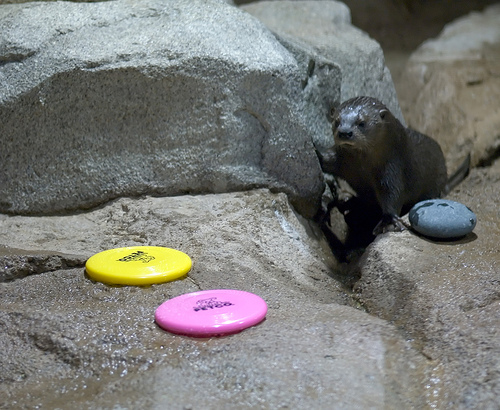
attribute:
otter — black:
[316, 91, 453, 241]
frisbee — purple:
[148, 277, 277, 352]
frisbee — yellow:
[82, 243, 194, 288]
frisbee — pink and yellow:
[81, 241, 196, 284]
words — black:
[187, 286, 231, 316]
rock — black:
[407, 196, 479, 241]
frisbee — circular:
[75, 203, 285, 380]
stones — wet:
[54, 317, 161, 406]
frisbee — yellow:
[78, 230, 198, 290]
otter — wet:
[327, 95, 448, 232]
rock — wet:
[21, 294, 107, 407]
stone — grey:
[3, 4, 329, 201]